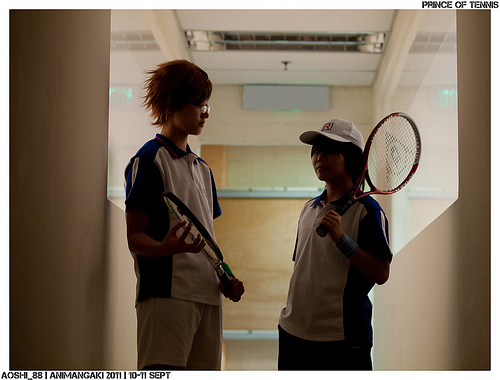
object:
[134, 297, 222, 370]
shorts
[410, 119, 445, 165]
ground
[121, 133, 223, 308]
jersey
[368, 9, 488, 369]
wall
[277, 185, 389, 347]
blue white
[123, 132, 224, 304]
blue white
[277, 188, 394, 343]
shirt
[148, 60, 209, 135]
head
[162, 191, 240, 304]
racket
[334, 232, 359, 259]
wristband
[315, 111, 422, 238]
racket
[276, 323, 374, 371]
pant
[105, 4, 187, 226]
window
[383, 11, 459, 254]
window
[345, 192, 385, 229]
shoulder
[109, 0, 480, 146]
ceiling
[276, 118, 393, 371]
boy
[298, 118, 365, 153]
cap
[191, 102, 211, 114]
specs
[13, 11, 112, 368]
pillar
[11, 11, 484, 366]
building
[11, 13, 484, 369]
photo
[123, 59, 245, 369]
boy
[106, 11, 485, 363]
hallway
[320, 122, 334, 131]
logo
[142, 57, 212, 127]
hair